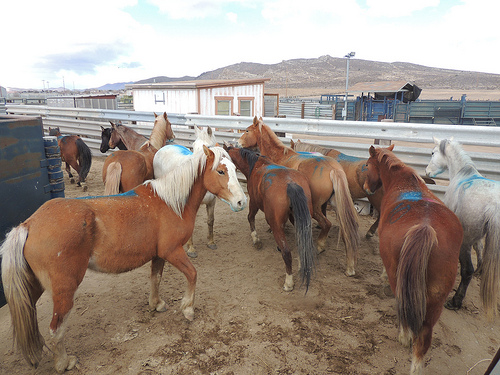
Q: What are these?
A: Horses.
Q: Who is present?
A: No one.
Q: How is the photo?
A: Clear.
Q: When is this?
A: Daytime.